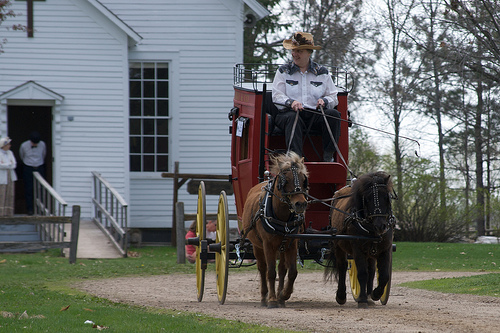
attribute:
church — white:
[2, 0, 269, 260]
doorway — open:
[7, 104, 50, 213]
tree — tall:
[444, 20, 494, 222]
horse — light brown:
[217, 158, 316, 288]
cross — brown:
[0, 2, 67, 46]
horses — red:
[207, 161, 319, 307]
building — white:
[0, 0, 267, 256]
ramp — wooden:
[22, 189, 125, 246]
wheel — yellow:
[194, 180, 208, 300]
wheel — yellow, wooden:
[215, 186, 228, 306]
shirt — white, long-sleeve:
[271, 62, 338, 109]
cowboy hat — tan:
[279, 30, 325, 50]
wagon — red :
[180, 55, 405, 314]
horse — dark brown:
[330, 172, 400, 306]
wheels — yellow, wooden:
[214, 187, 228, 299]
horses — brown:
[269, 174, 467, 305]